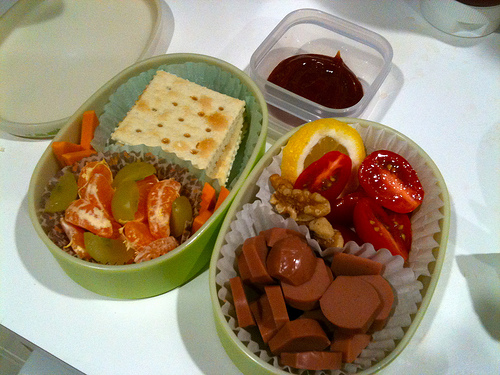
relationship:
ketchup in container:
[276, 39, 354, 119] [242, 10, 412, 116]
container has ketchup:
[242, 10, 412, 116] [276, 39, 354, 119]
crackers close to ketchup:
[126, 69, 246, 183] [276, 39, 354, 119]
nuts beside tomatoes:
[262, 172, 330, 240] [304, 153, 428, 248]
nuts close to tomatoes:
[262, 172, 330, 240] [304, 153, 428, 248]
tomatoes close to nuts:
[304, 153, 428, 248] [262, 172, 330, 240]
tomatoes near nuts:
[304, 153, 428, 248] [262, 172, 330, 240]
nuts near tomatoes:
[262, 172, 330, 240] [304, 153, 428, 248]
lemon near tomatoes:
[287, 117, 355, 182] [304, 153, 428, 248]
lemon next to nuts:
[287, 117, 355, 182] [262, 172, 330, 240]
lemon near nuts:
[287, 117, 355, 182] [262, 172, 330, 240]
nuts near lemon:
[262, 172, 330, 240] [287, 117, 355, 182]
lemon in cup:
[287, 117, 355, 182] [206, 118, 453, 361]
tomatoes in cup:
[304, 153, 428, 248] [206, 118, 453, 361]